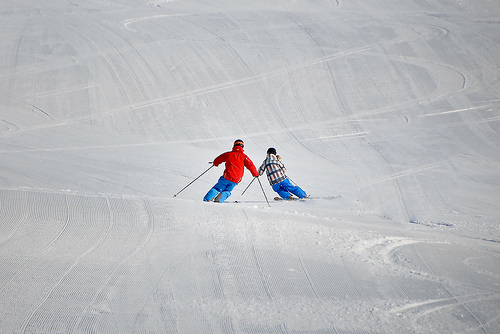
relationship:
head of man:
[233, 137, 245, 151] [202, 137, 258, 203]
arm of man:
[214, 152, 231, 168] [202, 137, 258, 203]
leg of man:
[206, 177, 225, 199] [202, 137, 258, 203]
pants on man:
[204, 171, 238, 203] [202, 137, 258, 203]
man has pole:
[202, 137, 258, 203] [175, 161, 216, 197]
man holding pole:
[202, 137, 258, 203] [175, 161, 216, 197]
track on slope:
[352, 234, 460, 332] [0, 1, 499, 333]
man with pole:
[202, 137, 258, 203] [175, 161, 216, 197]